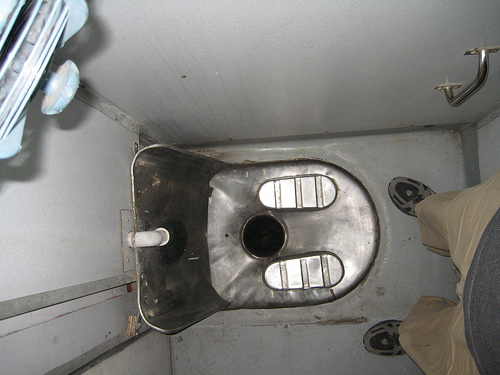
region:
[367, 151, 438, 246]
feet of a person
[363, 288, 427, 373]
feet of a person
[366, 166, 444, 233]
a feet of a person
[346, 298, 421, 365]
a feet of a person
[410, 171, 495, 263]
leg of a person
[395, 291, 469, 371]
leg of a person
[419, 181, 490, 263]
a leg of a person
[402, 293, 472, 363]
a leg of a person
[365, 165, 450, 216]
sneaker of a person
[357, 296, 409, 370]
sneaker of a person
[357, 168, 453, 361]
Man wearing shoes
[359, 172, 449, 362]
Man is wearing shoes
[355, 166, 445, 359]
Man wearing black and brown shoes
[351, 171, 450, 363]
Man is wearing black and brown shoes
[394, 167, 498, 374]
Man wearing pants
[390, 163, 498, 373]
Man is wearing pants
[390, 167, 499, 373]
Man wearing brown pants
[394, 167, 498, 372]
Man is wearing brown pants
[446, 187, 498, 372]
Man wearing a gray shirt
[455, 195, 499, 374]
Man is wearing a gray shirt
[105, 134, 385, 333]
a toilet of metal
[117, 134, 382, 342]
the toilet is old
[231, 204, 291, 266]
the whole of a toilet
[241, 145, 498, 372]
person stands in front a toilet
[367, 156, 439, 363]
a pair of old shoes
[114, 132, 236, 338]
lid of toilet is up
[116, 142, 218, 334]
lid of toilet is black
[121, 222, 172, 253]
a white tube on lid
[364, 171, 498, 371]
person wears brown pants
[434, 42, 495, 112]
the handle of door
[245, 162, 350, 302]
footprints on the toilet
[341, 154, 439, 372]
man is wearing gray and black shoes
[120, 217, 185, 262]
white pipe coming out of toilet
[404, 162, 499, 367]
man is wearing brown khaki pants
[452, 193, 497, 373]
man is wearing a gray shirt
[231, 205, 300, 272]
hole in the toilet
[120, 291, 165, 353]
small piece of brown wood on the wall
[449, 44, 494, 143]
silver hand railing on wall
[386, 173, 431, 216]
grey shoe of man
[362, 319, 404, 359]
grey shoe of man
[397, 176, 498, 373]
tan pants of man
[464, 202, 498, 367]
grey shirt of man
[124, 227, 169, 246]
white pipe on wall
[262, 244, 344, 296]
footprint on steel seat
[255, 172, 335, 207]
footprint on steel seat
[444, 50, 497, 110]
metal handle on door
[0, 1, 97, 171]
blue plastic thing on wall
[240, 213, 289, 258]
hole in metal seat